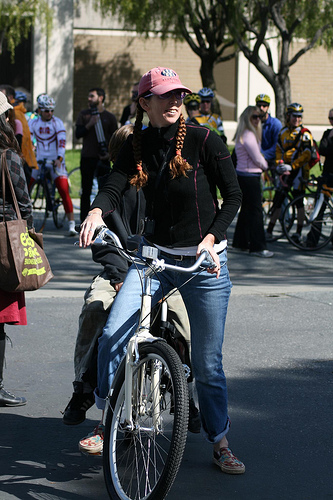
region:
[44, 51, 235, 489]
Two people are on a bicycle.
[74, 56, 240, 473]
A woman is sitting on the front of the bike.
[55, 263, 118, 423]
Another person is partially visible on the back of the bike.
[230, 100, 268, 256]
The woman is wearing a pink sweater.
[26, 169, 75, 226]
The man has on red pants.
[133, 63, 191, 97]
The woman is wearing a pink hat.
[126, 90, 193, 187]
The woman is wearing her hair in braids.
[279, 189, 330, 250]
The front wheel on a bicycle.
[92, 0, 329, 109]
Green trees next to a building.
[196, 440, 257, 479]
The woman is wearing a canvas shoe.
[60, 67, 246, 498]
girl riding a bike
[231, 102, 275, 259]
girl with long hair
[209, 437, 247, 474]
left foot on the ground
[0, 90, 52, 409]
woman holding brown bag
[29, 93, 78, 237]
man riding a bike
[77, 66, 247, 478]
young girl wearing blue jeans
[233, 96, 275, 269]
woman standing on the road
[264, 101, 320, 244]
man wearing a helmet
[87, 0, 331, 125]
two trees in the background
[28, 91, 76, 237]
young man wearing sunglasses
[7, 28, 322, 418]
people and bicycles gathered on road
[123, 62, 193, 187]
woman with long braided red hair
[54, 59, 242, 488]
woman on bicycle with young passenger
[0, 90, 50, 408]
woman with brown tote bag walking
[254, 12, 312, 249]
bicyclists in helmets and riding gear under a tree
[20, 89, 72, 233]
bicyclist in red and white outfit on bike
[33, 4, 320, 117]
brown and white building behind people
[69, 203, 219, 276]
hands holding onto ends of handlebar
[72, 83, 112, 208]
man in dark clothes looking sideways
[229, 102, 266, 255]
woman in pink top standing sideways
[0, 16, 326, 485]
sunny biking event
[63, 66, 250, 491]
woman and child on bike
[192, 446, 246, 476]
multi colored slip on shoe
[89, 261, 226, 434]
woman's blue jeans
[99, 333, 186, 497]
black bike wheel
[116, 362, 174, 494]
spoke of the bicycle wheel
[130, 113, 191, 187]
woman's hair braids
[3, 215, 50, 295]
brown and yellow grocery bag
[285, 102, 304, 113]
silver and yellow bicyclist helmet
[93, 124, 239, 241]
black long sleeved shirt with purple accents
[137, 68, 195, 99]
a pink baseball cap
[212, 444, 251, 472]
the shoe of a woman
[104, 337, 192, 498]
a bike tire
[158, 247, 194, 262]
a woman's belt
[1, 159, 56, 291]
a large brown bag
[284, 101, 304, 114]
a colorful bike helmet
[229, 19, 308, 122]
part of a gray tree branch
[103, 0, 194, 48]
green tree leaves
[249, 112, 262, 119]
dark black sunglasses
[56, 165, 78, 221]
the leg of a man